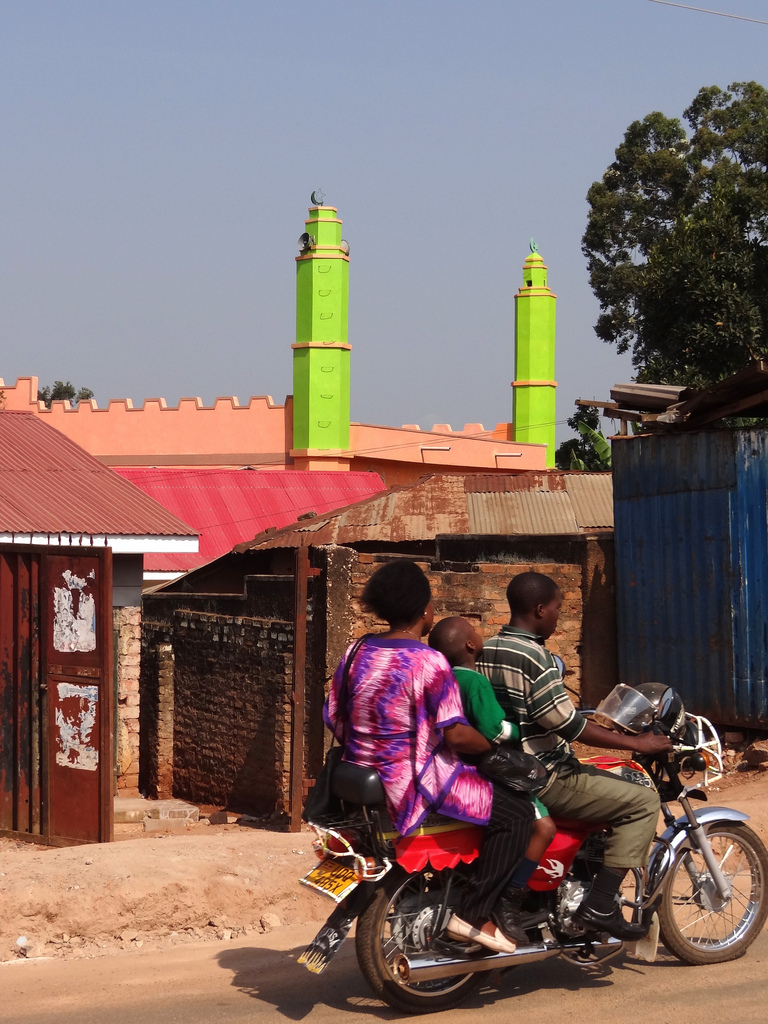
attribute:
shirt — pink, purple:
[325, 634, 495, 831]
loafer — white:
[443, 906, 517, 955]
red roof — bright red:
[118, 463, 384, 588]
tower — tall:
[291, 184, 359, 470]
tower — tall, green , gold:
[512, 233, 559, 472]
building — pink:
[1, 364, 555, 506]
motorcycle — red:
[280, 683, 766, 1009]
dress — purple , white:
[322, 639, 495, 843]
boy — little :
[430, 614, 526, 786]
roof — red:
[96, 456, 388, 579]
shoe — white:
[441, 910, 517, 959]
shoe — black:
[570, 901, 650, 942]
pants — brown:
[528, 761, 660, 871]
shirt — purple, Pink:
[328, 635, 491, 818]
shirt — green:
[454, 668, 507, 737]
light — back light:
[310, 820, 379, 886]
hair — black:
[365, 559, 436, 631]